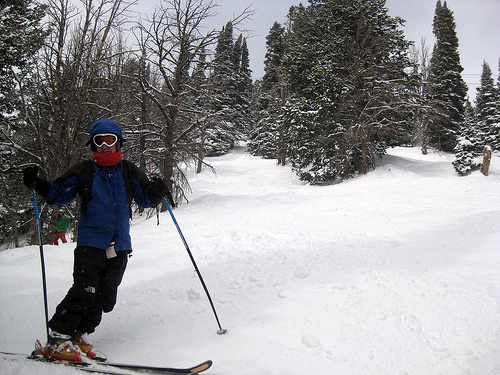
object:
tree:
[475, 58, 498, 150]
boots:
[47, 329, 93, 364]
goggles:
[93, 134, 118, 147]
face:
[96, 134, 116, 154]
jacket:
[37, 159, 150, 253]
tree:
[417, 0, 463, 148]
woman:
[22, 119, 170, 368]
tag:
[106, 240, 118, 259]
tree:
[262, 0, 413, 186]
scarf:
[92, 150, 122, 166]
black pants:
[48, 247, 128, 339]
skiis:
[0, 351, 213, 373]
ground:
[0, 144, 500, 375]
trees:
[146, 0, 198, 198]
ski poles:
[151, 175, 227, 335]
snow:
[0, 145, 499, 375]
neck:
[93, 151, 124, 166]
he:
[22, 119, 169, 364]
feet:
[46, 330, 90, 362]